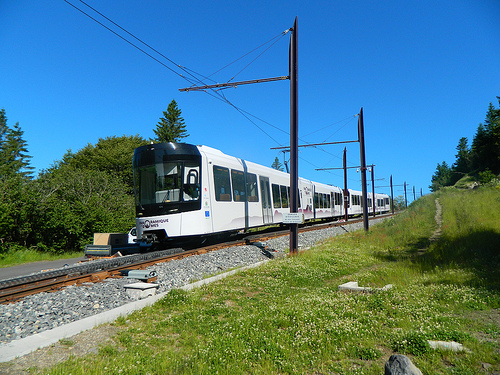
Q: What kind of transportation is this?
A: A train.